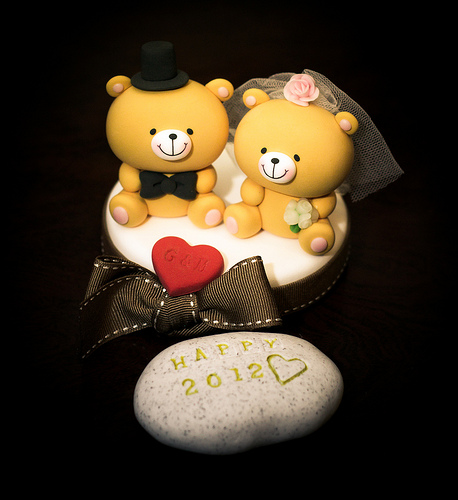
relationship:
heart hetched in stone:
[266, 354, 308, 384] [135, 329, 348, 457]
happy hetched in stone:
[172, 338, 277, 372] [135, 329, 348, 457]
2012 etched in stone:
[183, 362, 263, 397] [135, 329, 348, 457]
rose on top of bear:
[281, 73, 319, 108] [224, 86, 360, 259]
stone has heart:
[135, 329, 348, 457] [266, 354, 308, 384]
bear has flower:
[224, 86, 360, 259] [281, 199, 312, 233]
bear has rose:
[224, 86, 360, 259] [281, 73, 319, 108]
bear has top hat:
[100, 41, 234, 227] [126, 41, 188, 92]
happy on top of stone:
[172, 338, 277, 372] [135, 329, 348, 457]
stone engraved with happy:
[135, 329, 348, 457] [172, 338, 277, 372]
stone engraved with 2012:
[135, 329, 348, 457] [183, 362, 263, 397]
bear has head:
[100, 41, 234, 227] [104, 77, 236, 174]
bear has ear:
[100, 41, 234, 227] [106, 74, 131, 97]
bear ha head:
[224, 86, 360, 259] [233, 89, 359, 198]